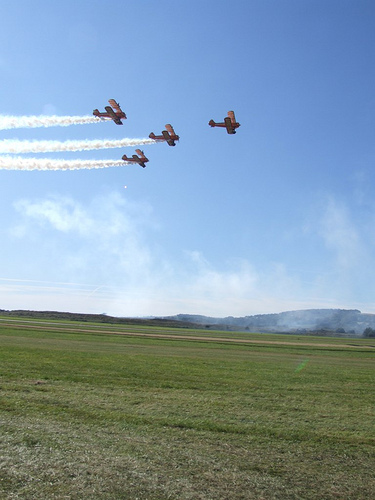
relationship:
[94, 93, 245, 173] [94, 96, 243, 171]
planes are in formation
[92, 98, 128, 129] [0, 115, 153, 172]
plane has smoke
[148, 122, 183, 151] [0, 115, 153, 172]
plane has smoke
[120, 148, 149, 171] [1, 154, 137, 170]
plane has smoke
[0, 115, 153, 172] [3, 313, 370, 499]
smoke close to ground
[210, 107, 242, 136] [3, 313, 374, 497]
plane over field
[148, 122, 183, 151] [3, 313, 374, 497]
plane over field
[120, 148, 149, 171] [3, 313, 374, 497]
plane over field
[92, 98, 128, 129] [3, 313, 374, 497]
plane over field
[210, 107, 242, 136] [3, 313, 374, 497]
plane flies over field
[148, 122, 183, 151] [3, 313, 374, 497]
plane flies over field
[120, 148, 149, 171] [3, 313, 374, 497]
plane flies over field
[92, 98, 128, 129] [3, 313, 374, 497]
plane flies over field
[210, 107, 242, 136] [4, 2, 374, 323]
plane in sky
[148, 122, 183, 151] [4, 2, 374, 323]
plane in sky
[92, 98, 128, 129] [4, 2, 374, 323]
plane in sky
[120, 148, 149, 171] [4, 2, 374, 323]
plane in sky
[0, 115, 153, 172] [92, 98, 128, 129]
smoke left by plane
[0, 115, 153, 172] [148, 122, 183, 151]
smoke left by plane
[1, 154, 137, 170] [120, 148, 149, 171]
smoke left by plane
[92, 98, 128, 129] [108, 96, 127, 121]
plane has wing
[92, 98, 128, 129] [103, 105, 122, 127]
plane has wing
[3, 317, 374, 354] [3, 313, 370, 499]
dirt on ground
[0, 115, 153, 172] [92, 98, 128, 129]
smoke from plane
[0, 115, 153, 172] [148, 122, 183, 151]
smoke from plane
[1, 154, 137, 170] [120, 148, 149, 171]
smoke from plane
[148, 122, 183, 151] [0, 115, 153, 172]
plane creates smoke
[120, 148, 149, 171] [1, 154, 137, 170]
plane creates smoke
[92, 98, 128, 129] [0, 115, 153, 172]
plane creates smoke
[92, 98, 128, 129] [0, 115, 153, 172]
plane makes smoke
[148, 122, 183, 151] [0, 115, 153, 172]
plane makes smoke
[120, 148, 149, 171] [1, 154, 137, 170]
plane makes smoke